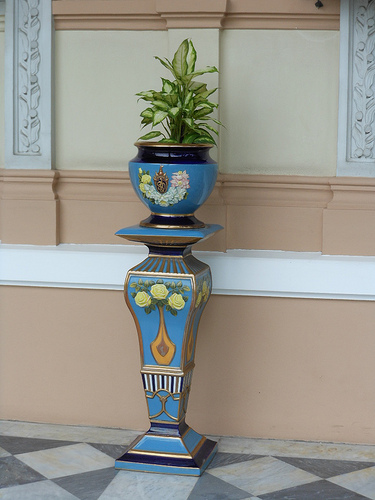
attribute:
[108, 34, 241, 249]
vase — decorated, decorative, tall, different colors, enamel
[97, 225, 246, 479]
stand — decorated, blue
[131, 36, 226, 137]
plant — green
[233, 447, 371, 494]
floor — white, grey, marble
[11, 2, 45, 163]
design — white